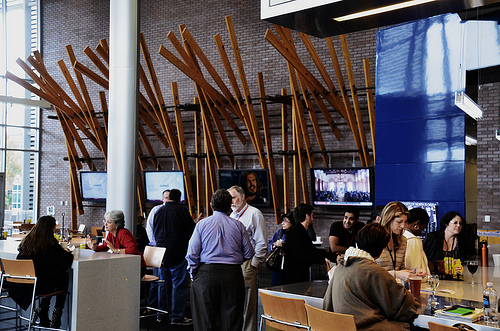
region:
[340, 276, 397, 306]
part of a jumper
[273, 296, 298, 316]
section of a wooden chair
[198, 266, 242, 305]
part of a dark trouser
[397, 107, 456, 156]
part of a blue board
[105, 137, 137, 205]
part of a white pole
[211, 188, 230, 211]
part of a man's hair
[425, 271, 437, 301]
a trophy on the desk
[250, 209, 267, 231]
part of a light shirt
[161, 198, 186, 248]
part of a black shirt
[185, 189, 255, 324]
man with his hand in his pocket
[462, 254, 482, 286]
glass of red wine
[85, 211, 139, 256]
lady in a red shirt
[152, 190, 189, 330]
man wearing blue jeans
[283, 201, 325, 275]
man with a black beard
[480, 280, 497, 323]
plastic bottle with water in it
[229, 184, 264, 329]
man in a white dress shirt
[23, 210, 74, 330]
woman sitting in a chair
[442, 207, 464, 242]
woman wearing eye glasses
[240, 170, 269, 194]
man on tv in the background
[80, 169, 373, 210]
row of flat screen televisions on the wall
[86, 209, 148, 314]
woman wearing glasses is sitting behind a desk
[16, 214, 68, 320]
woman with long hair is sitting in front of desk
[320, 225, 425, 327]
woman wearing a tan coat sitting at a table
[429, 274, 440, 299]
glass full of water sitting on table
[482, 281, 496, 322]
water bottle sitting on table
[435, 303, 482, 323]
book laying near water bottle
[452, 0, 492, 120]
light suspending from ceiling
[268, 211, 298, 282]
woman holding a bag on her shoulder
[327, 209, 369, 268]
man wearing a black shirt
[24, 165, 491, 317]
people standing and sitting in a bar/restaurant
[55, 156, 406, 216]
flat screen tvs along wall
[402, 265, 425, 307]
glass of beer on bar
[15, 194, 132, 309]
two women sitting at table talking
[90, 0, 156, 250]
large white beam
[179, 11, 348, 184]
decorative wooden slats on wall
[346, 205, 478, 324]
three people sitting at the bar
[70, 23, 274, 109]
red brick wall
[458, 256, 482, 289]
glass of red wine on bar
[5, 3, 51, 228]
large tall windows with light shining through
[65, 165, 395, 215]
four televisions on wall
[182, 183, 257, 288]
standing man in purple shirt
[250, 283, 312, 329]
bar stool with wood back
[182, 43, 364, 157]
bent wood decoration on wall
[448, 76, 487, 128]
light hanging over bar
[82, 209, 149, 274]
sitting woman with red shirt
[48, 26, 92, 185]
high brick wall of restaurant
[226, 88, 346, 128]
black rods holding wood decor